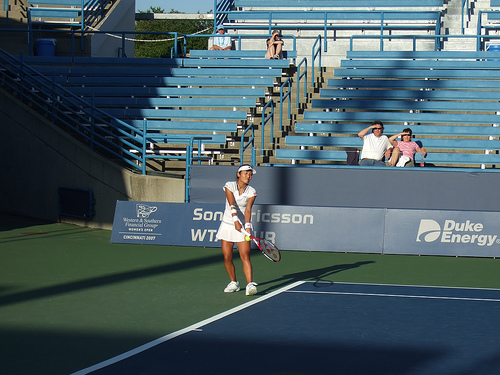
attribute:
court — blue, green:
[4, 217, 495, 373]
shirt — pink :
[395, 135, 419, 160]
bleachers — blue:
[275, 36, 498, 182]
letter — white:
[202, 222, 218, 242]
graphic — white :
[136, 202, 158, 219]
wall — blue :
[109, 199, 499, 256]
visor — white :
[239, 164, 259, 174]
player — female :
[190, 149, 297, 299]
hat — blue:
[215, 23, 226, 30]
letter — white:
[452, 221, 464, 235]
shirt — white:
[358, 131, 392, 159]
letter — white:
[419, 214, 488, 256]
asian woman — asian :
[179, 142, 288, 309]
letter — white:
[440, 229, 452, 244]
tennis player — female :
[217, 164, 259, 298]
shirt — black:
[267, 37, 280, 46]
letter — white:
[192, 206, 203, 222]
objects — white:
[228, 205, 239, 224]